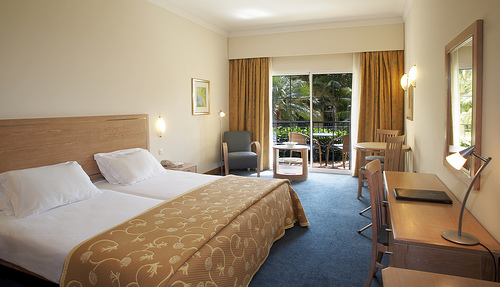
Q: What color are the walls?
A: White.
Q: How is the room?
A: Clean.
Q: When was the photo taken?
A: Daytime.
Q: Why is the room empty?
A: There is no one.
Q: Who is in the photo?
A: Nobody.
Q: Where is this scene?
A: In the hotel room.